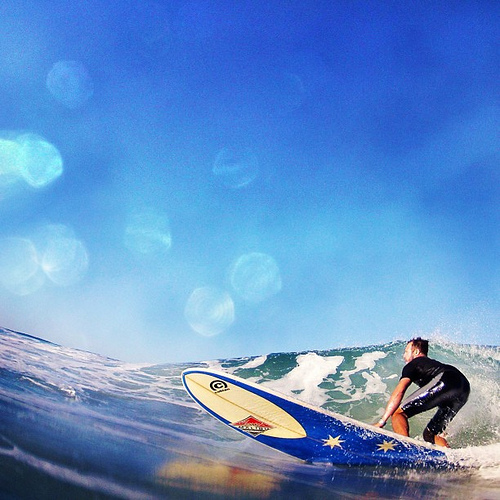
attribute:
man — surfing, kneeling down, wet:
[374, 337, 473, 451]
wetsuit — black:
[401, 356, 470, 442]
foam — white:
[257, 349, 402, 416]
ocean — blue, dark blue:
[3, 323, 499, 499]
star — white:
[322, 433, 350, 451]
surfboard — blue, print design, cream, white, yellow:
[180, 366, 454, 468]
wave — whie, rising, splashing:
[112, 340, 499, 478]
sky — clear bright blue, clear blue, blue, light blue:
[1, 1, 495, 365]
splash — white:
[397, 313, 488, 346]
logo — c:
[210, 377, 229, 395]